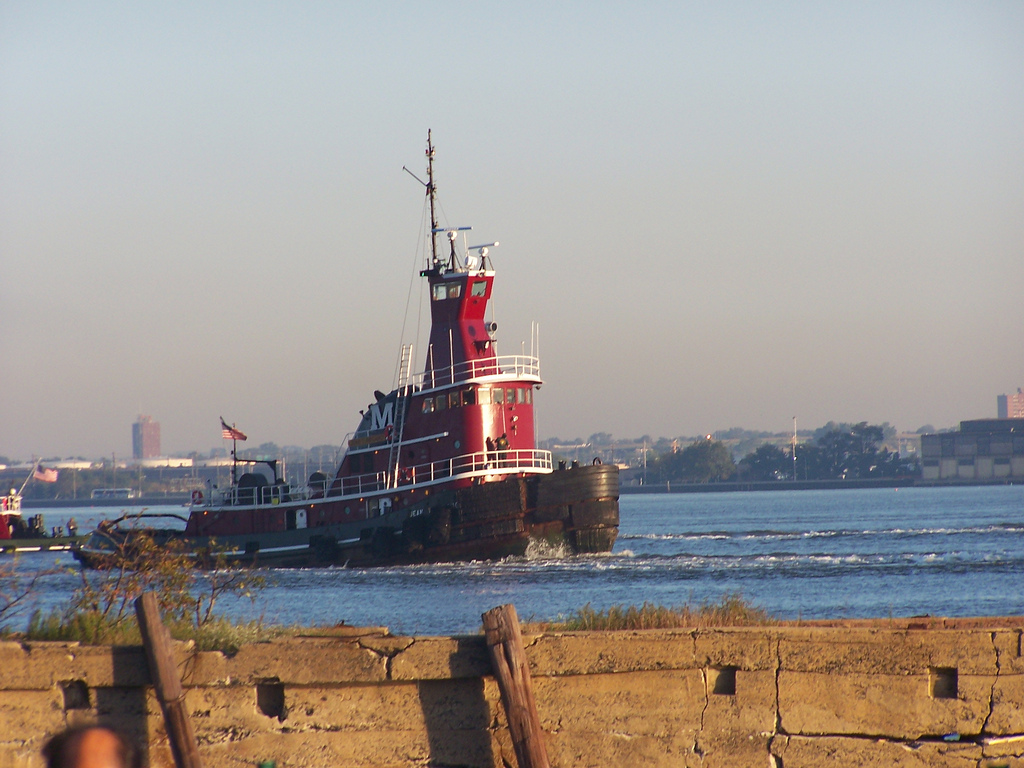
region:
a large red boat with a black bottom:
[72, 130, 622, 571]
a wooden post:
[482, 603, 546, 766]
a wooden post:
[135, 595, 196, 764]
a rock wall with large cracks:
[5, 613, 1018, 763]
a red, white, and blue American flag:
[212, 411, 251, 443]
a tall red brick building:
[128, 414, 163, 459]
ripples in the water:
[195, 515, 1021, 579]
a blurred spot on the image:
[40, 720, 140, 766]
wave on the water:
[691, 544, 721, 557]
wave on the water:
[778, 543, 832, 567]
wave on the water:
[751, 522, 780, 532]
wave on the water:
[844, 524, 890, 537]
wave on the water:
[55, 556, 94, 575]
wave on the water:
[822, 552, 893, 604]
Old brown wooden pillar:
[468, 584, 570, 759]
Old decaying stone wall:
[729, 648, 951, 750]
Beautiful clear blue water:
[783, 530, 998, 604]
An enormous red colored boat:
[163, 183, 631, 572]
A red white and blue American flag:
[204, 402, 265, 459]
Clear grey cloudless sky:
[618, 214, 973, 370]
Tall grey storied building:
[128, 401, 182, 468]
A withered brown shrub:
[106, 519, 211, 593]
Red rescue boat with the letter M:
[70, 126, 618, 570]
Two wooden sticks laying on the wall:
[133, 595, 549, 766]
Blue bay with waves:
[6, 488, 1022, 635]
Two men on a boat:
[482, 436, 505, 466]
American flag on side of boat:
[61, 129, 621, 570]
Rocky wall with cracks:
[4, 622, 1020, 766]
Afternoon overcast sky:
[0, 1, 1022, 463]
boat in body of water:
[58, 115, 651, 567]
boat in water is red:
[42, 115, 646, 567]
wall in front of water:
[9, 574, 1022, 767]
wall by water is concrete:
[3, 597, 1022, 766]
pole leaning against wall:
[469, 593, 559, 767]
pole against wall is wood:
[471, 594, 555, 766]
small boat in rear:
[6, 447, 83, 569]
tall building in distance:
[123, 412, 162, 464]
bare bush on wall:
[45, 507, 292, 650]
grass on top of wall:
[19, 587, 811, 658]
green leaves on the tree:
[149, 549, 248, 630]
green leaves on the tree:
[836, 429, 847, 446]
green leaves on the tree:
[813, 411, 851, 457]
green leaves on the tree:
[634, 426, 686, 446]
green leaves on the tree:
[693, 434, 739, 483]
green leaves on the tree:
[807, 396, 850, 445]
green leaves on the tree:
[743, 426, 789, 490]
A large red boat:
[262, 174, 575, 539]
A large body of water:
[549, 458, 938, 621]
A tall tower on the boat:
[411, 183, 542, 367]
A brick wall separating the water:
[666, 616, 952, 756]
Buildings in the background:
[592, 344, 986, 516]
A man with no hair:
[34, 733, 177, 753]